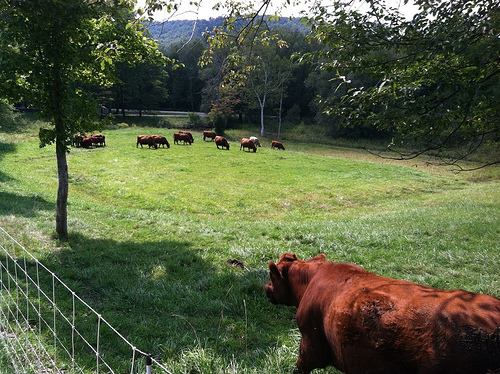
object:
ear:
[267, 260, 281, 284]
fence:
[0, 221, 176, 374]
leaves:
[88, 9, 119, 38]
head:
[264, 252, 327, 309]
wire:
[0, 238, 167, 372]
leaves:
[436, 92, 451, 105]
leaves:
[387, 96, 401, 110]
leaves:
[336, 92, 348, 104]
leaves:
[469, 114, 478, 132]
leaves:
[303, 103, 320, 110]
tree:
[290, 0, 499, 174]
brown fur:
[289, 259, 499, 373]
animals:
[70, 130, 286, 152]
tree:
[209, 33, 299, 139]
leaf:
[96, 59, 108, 72]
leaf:
[128, 52, 142, 64]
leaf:
[37, 126, 57, 148]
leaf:
[85, 17, 96, 30]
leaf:
[169, 59, 186, 73]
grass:
[1, 107, 500, 373]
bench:
[0, 120, 499, 373]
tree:
[0, 0, 190, 241]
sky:
[127, 1, 499, 42]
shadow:
[0, 229, 297, 374]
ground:
[2, 114, 499, 374]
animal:
[264, 251, 500, 374]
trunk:
[251, 72, 271, 138]